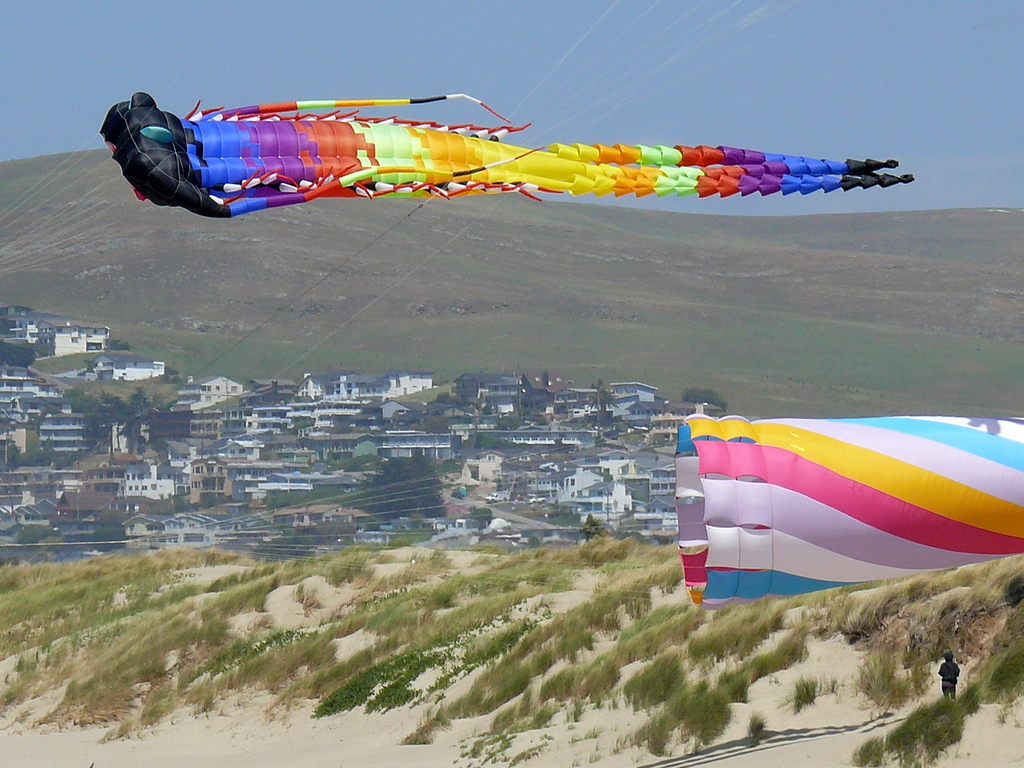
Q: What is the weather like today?
A: It is clear.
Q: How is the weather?
A: It is clear.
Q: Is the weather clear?
A: Yes, it is clear.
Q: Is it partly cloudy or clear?
A: It is clear.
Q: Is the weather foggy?
A: No, it is clear.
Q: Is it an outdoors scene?
A: Yes, it is outdoors.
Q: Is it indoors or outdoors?
A: It is outdoors.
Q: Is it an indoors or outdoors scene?
A: It is outdoors.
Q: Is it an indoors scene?
A: No, it is outdoors.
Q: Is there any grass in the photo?
A: Yes, there is grass.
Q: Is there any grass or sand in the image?
A: Yes, there is grass.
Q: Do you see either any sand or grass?
A: Yes, there is grass.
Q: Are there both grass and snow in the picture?
A: No, there is grass but no snow.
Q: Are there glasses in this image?
A: No, there are no glasses.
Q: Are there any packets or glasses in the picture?
A: No, there are no glasses or packets.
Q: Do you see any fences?
A: No, there are no fences.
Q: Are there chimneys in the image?
A: No, there are no chimneys.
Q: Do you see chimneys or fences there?
A: No, there are no chimneys or fences.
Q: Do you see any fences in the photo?
A: No, there are no fences.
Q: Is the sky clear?
A: Yes, the sky is clear.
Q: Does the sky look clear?
A: Yes, the sky is clear.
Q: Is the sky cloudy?
A: No, the sky is clear.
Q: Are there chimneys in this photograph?
A: No, there are no chimneys.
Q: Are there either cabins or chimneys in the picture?
A: No, there are no chimneys or cabins.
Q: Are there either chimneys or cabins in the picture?
A: No, there are no chimneys or cabins.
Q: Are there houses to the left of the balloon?
A: Yes, there is a house to the left of the balloon.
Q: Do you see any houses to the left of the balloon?
A: Yes, there is a house to the left of the balloon.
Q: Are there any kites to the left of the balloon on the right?
A: No, there is a house to the left of the balloon.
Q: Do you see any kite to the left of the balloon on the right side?
A: No, there is a house to the left of the balloon.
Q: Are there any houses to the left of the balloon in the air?
A: Yes, there is a house to the left of the balloon.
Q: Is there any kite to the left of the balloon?
A: No, there is a house to the left of the balloon.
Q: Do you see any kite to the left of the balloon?
A: No, there is a house to the left of the balloon.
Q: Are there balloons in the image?
A: Yes, there is a balloon.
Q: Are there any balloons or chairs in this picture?
A: Yes, there is a balloon.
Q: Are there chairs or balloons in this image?
A: Yes, there is a balloon.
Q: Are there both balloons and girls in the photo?
A: No, there is a balloon but no girls.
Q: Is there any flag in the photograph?
A: No, there are no flags.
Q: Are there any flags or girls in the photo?
A: No, there are no flags or girls.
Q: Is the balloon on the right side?
A: Yes, the balloon is on the right of the image.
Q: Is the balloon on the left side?
A: No, the balloon is on the right of the image.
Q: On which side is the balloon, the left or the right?
A: The balloon is on the right of the image.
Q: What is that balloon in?
A: The balloon is in the air.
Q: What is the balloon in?
A: The balloon is in the air.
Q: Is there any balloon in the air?
A: Yes, there is a balloon in the air.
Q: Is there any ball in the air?
A: No, there is a balloon in the air.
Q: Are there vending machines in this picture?
A: No, there are no vending machines.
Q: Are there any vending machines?
A: No, there are no vending machines.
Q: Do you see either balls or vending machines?
A: No, there are no vending machines or balls.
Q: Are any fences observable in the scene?
A: No, there are no fences.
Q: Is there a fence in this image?
A: No, there are no fences.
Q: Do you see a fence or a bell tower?
A: No, there are no fences or bell towers.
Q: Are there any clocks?
A: No, there are no clocks.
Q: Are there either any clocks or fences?
A: No, there are no clocks or fences.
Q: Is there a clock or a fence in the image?
A: No, there are no clocks or fences.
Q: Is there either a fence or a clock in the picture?
A: No, there are no clocks or fences.